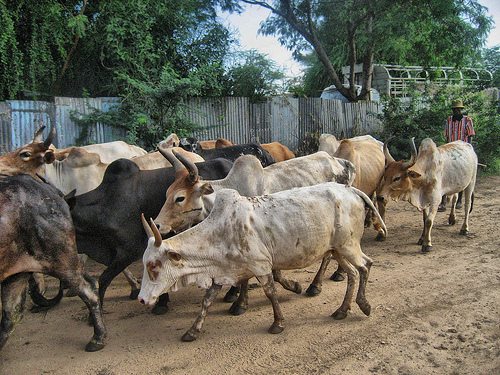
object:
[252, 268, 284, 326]
leg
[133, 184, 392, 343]
cow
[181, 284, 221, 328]
leg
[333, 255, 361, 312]
leg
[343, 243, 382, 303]
leg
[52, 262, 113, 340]
leg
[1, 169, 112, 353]
cow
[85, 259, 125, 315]
leg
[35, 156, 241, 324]
cow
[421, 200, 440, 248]
leg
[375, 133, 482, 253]
cow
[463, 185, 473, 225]
leg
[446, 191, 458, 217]
leg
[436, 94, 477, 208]
man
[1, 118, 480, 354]
group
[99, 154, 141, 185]
hump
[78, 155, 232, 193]
back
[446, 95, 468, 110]
hat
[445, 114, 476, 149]
shirt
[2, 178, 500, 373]
dirt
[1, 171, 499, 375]
ground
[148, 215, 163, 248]
horns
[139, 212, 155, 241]
horns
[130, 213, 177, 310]
head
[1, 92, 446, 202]
fence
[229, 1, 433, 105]
trees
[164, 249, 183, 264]
ear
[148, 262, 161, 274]
eye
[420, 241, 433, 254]
hoof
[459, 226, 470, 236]
hoof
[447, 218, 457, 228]
hoof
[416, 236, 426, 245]
hoof